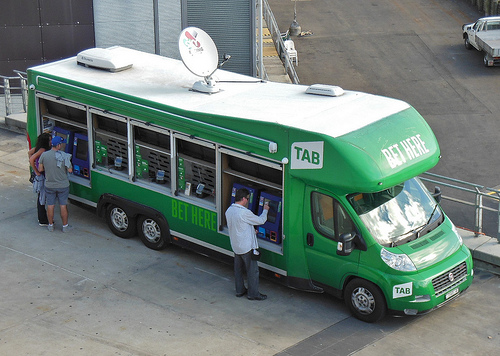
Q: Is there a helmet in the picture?
A: No, there are no helmets.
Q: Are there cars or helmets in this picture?
A: No, there are no helmets or cars.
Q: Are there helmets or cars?
A: No, there are no helmets or cars.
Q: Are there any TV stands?
A: No, there are no TV stands.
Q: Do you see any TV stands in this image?
A: No, there are no TV stands.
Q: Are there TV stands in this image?
A: No, there are no TV stands.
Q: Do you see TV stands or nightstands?
A: No, there are no TV stands or nightstands.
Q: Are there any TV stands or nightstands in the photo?
A: No, there are no TV stands or nightstands.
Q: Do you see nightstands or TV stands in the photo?
A: No, there are no TV stands or nightstands.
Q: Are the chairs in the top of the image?
A: Yes, the chairs are in the top of the image.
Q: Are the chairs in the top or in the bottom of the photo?
A: The chairs are in the top of the image.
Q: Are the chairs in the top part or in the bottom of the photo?
A: The chairs are in the top of the image.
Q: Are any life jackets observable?
A: No, there are no life jackets.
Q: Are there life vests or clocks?
A: No, there are no life vests or clocks.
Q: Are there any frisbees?
A: No, there are no frisbees.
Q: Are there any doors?
A: Yes, there is a door.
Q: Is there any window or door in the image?
A: Yes, there is a door.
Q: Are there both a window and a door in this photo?
A: Yes, there are both a door and a window.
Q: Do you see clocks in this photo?
A: No, there are no clocks.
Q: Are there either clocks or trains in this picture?
A: No, there are no clocks or trains.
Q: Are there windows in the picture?
A: Yes, there is a window.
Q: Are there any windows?
A: Yes, there is a window.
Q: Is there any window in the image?
A: Yes, there is a window.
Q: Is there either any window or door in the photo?
A: Yes, there is a window.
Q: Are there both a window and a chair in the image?
A: Yes, there are both a window and a chair.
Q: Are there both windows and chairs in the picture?
A: Yes, there are both a window and a chair.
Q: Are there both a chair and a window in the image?
A: Yes, there are both a window and a chair.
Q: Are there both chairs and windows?
A: Yes, there are both a window and a chair.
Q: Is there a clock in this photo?
A: No, there are no clocks.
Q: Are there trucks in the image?
A: Yes, there is a truck.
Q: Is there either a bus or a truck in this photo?
A: Yes, there is a truck.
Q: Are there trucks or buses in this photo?
A: Yes, there is a truck.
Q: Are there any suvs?
A: No, there are no suvs.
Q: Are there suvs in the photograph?
A: No, there are no suvs.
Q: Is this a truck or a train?
A: This is a truck.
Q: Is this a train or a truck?
A: This is a truck.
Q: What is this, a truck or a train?
A: This is a truck.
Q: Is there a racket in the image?
A: No, there are no rackets.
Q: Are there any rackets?
A: No, there are no rackets.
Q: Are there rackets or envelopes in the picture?
A: No, there are no rackets or envelopes.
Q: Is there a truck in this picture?
A: Yes, there is a truck.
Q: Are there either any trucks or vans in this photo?
A: Yes, there is a truck.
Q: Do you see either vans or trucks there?
A: Yes, there is a truck.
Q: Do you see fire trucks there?
A: No, there are no fire trucks.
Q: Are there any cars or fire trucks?
A: No, there are no fire trucks or cars.